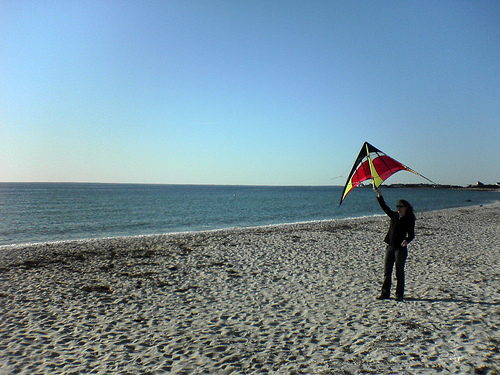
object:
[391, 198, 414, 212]
head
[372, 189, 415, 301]
person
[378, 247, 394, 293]
leg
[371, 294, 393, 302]
feet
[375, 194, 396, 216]
arm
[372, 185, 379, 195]
hand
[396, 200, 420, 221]
hair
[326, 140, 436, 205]
kite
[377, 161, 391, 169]
pink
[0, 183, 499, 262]
ocean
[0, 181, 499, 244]
clean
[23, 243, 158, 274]
dark sea weed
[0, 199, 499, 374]
beach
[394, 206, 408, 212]
sunglasses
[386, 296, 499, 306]
shadow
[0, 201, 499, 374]
sand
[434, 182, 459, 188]
tree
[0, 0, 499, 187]
clear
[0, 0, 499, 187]
sky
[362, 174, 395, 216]
lifting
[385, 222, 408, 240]
dark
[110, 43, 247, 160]
sunny